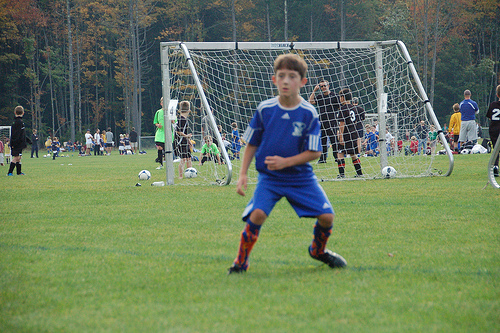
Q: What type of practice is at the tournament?
A: A soccer tournament.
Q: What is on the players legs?
A: Socks.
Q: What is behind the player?
A: Large net.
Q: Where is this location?
A: Soccer field.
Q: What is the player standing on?
A: Grass.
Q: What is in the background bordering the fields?
A: Trees.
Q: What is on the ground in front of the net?
A: Balls.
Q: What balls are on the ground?
A: Soccer.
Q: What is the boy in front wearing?
A: Blue and white uniform.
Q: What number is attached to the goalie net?
A: 4.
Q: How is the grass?
A: Green and neatly trimmed.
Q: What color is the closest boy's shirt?
A: Blue.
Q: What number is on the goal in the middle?
A: 4.